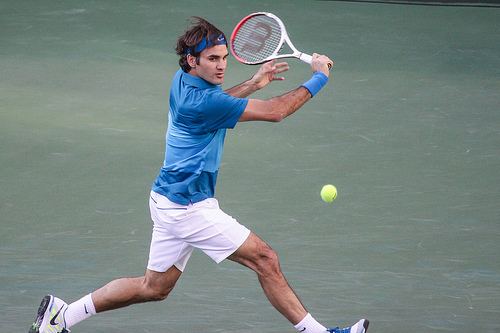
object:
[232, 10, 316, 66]
tennis racket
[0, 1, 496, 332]
court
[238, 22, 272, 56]
w logo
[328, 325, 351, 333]
shoelaces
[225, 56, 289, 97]
arm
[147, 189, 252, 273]
shorts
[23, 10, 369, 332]
man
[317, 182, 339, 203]
ball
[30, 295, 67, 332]
shoe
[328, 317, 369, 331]
shoe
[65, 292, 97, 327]
sock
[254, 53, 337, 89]
hands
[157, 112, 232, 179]
straps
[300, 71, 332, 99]
band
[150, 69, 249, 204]
shirt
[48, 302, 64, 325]
logo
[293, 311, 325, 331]
sock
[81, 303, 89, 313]
logo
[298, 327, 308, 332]
logo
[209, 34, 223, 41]
logo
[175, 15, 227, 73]
hair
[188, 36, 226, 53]
band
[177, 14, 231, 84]
head